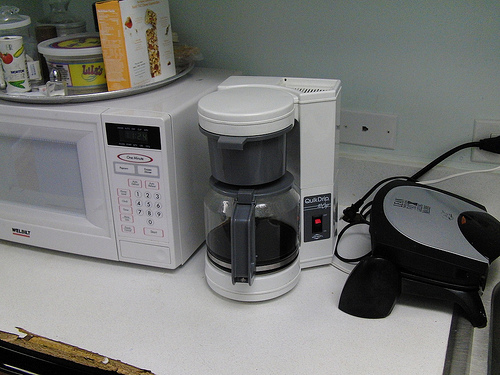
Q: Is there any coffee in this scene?
A: Yes, there is coffee.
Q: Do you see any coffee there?
A: Yes, there is coffee.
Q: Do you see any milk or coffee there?
A: Yes, there is coffee.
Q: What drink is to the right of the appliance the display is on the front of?
A: The drink is coffee.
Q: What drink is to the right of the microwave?
A: The drink is coffee.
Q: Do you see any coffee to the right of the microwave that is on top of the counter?
A: Yes, there is coffee to the right of the microwave.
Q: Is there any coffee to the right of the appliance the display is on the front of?
A: Yes, there is coffee to the right of the microwave.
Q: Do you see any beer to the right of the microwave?
A: No, there is coffee to the right of the microwave.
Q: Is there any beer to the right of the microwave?
A: No, there is coffee to the right of the microwave.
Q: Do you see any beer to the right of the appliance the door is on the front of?
A: No, there is coffee to the right of the microwave.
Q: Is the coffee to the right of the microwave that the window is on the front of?
A: Yes, the coffee is to the right of the microwave.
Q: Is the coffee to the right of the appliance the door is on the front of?
A: Yes, the coffee is to the right of the microwave.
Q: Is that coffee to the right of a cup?
A: No, the coffee is to the right of the microwave.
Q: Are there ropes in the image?
A: No, there are no ropes.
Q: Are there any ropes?
A: No, there are no ropes.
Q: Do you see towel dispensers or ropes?
A: No, there are no ropes or towel dispensers.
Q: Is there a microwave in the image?
A: Yes, there is a microwave.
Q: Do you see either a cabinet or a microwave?
A: Yes, there is a microwave.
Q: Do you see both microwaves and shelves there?
A: No, there is a microwave but no shelves.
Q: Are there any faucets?
A: No, there are no faucets.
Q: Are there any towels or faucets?
A: No, there are no faucets or towels.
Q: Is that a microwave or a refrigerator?
A: That is a microwave.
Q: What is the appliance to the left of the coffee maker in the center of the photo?
A: The appliance is a microwave.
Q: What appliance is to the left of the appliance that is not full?
A: The appliance is a microwave.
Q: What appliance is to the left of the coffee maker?
A: The appliance is a microwave.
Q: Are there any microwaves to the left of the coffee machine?
A: Yes, there is a microwave to the left of the coffee machine.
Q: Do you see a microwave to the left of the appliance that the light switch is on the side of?
A: Yes, there is a microwave to the left of the coffee machine.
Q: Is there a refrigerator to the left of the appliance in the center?
A: No, there is a microwave to the left of the coffee maker.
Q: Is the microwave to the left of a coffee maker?
A: Yes, the microwave is to the left of a coffee maker.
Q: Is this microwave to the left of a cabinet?
A: No, the microwave is to the left of a coffee maker.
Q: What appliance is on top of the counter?
A: The appliance is a microwave.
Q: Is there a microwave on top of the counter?
A: Yes, there is a microwave on top of the counter.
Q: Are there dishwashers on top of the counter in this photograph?
A: No, there is a microwave on top of the counter.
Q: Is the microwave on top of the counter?
A: Yes, the microwave is on top of the counter.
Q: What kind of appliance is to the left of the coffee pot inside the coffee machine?
A: The appliance is a microwave.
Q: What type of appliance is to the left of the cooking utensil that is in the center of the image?
A: The appliance is a microwave.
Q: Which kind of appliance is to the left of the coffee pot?
A: The appliance is a microwave.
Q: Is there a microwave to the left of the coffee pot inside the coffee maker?
A: Yes, there is a microwave to the left of the coffee pot.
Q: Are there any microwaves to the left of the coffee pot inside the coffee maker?
A: Yes, there is a microwave to the left of the coffee pot.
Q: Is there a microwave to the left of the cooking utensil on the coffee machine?
A: Yes, there is a microwave to the left of the coffee pot.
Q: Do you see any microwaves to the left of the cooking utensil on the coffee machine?
A: Yes, there is a microwave to the left of the coffee pot.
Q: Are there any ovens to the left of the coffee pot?
A: No, there is a microwave to the left of the coffee pot.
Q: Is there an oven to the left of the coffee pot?
A: No, there is a microwave to the left of the coffee pot.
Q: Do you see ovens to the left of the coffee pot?
A: No, there is a microwave to the left of the coffee pot.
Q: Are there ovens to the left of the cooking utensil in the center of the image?
A: No, there is a microwave to the left of the coffee pot.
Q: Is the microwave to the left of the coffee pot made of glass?
A: Yes, the microwave is to the left of the coffee pot.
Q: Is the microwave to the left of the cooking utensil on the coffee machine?
A: Yes, the microwave is to the left of the coffee pot.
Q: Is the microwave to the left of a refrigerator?
A: No, the microwave is to the left of the coffee pot.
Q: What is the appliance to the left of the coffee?
A: The appliance is a microwave.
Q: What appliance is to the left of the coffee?
A: The appliance is a microwave.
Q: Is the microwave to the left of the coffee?
A: Yes, the microwave is to the left of the coffee.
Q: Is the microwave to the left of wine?
A: No, the microwave is to the left of the coffee.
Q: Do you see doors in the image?
A: Yes, there is a door.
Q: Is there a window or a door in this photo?
A: Yes, there is a door.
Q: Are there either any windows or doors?
A: Yes, there is a door.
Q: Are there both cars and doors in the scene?
A: No, there is a door but no cars.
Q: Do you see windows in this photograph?
A: Yes, there is a window.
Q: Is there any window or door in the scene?
A: Yes, there is a window.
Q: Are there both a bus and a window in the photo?
A: No, there is a window but no buses.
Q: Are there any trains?
A: No, there are no trains.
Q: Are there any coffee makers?
A: Yes, there is a coffee maker.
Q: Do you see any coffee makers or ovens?
A: Yes, there is a coffee maker.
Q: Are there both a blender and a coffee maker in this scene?
A: No, there is a coffee maker but no blenders.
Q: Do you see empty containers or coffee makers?
A: Yes, there is an empty coffee maker.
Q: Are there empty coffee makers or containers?
A: Yes, there is an empty coffee maker.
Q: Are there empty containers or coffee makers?
A: Yes, there is an empty coffee maker.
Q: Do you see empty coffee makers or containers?
A: Yes, there is an empty coffee maker.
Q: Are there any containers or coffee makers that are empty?
A: Yes, the coffee maker is empty.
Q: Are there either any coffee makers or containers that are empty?
A: Yes, the coffee maker is empty.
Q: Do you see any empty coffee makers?
A: Yes, there is an empty coffee maker.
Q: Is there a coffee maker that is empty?
A: Yes, there is a coffee maker that is empty.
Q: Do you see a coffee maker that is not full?
A: Yes, there is a empty coffee maker.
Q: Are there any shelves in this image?
A: No, there are no shelves.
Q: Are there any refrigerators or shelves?
A: No, there are no shelves or refrigerators.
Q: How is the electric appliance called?
A: The appliance is a coffee maker.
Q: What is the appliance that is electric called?
A: The appliance is a coffee maker.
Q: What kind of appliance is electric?
A: The appliance is a coffee maker.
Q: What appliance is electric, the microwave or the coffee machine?
A: The coffee machine is electric.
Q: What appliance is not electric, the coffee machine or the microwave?
A: The microwave is not electric.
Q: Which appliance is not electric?
A: The appliance is a microwave.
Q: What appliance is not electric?
A: The appliance is a microwave.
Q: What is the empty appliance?
A: The appliance is a coffee maker.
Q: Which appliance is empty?
A: The appliance is a coffee maker.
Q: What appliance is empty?
A: The appliance is a coffee maker.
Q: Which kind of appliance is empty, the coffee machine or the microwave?
A: The coffee machine is empty.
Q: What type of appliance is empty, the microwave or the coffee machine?
A: The coffee machine is empty.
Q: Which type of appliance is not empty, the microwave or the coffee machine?
A: The microwave is not empty.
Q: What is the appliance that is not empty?
A: The appliance is a microwave.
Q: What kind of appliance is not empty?
A: The appliance is a microwave.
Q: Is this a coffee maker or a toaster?
A: This is a coffee maker.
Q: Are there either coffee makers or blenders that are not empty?
A: No, there is a coffee maker but it is empty.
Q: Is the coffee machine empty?
A: Yes, the coffee machine is empty.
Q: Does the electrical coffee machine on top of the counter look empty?
A: Yes, the coffee maker is empty.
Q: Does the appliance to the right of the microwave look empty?
A: Yes, the coffee maker is empty.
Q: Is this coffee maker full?
A: No, the coffee maker is empty.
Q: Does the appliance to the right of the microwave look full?
A: No, the coffee maker is empty.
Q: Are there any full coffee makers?
A: No, there is a coffee maker but it is empty.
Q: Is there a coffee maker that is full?
A: No, there is a coffee maker but it is empty.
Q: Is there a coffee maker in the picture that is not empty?
A: No, there is a coffee maker but it is empty.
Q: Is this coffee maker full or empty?
A: The coffee maker is empty.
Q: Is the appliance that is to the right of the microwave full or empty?
A: The coffee maker is empty.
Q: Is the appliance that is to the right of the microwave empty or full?
A: The coffee maker is empty.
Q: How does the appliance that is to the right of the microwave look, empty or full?
A: The coffee maker is empty.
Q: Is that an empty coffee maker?
A: Yes, that is an empty coffee maker.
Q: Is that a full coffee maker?
A: No, that is an empty coffee maker.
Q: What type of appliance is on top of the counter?
A: The appliance is a coffee maker.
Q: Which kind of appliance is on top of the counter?
A: The appliance is a coffee maker.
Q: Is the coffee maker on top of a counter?
A: Yes, the coffee maker is on top of a counter.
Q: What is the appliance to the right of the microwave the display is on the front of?
A: The appliance is a coffee maker.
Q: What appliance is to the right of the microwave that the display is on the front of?
A: The appliance is a coffee maker.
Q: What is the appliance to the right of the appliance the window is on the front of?
A: The appliance is a coffee maker.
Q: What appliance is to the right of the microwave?
A: The appliance is a coffee maker.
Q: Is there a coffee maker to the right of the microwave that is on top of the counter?
A: Yes, there is a coffee maker to the right of the microwave.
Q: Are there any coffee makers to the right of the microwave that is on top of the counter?
A: Yes, there is a coffee maker to the right of the microwave.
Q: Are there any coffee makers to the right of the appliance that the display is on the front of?
A: Yes, there is a coffee maker to the right of the microwave.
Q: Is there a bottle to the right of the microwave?
A: No, there is a coffee maker to the right of the microwave.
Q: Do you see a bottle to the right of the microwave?
A: No, there is a coffee maker to the right of the microwave.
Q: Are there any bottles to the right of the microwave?
A: No, there is a coffee maker to the right of the microwave.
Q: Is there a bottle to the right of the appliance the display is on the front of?
A: No, there is a coffee maker to the right of the microwave.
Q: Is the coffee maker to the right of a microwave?
A: Yes, the coffee maker is to the right of a microwave.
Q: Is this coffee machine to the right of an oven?
A: No, the coffee machine is to the right of a microwave.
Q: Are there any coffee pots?
A: Yes, there is a coffee pot.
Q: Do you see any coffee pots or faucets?
A: Yes, there is a coffee pot.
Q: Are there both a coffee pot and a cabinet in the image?
A: No, there is a coffee pot but no cabinets.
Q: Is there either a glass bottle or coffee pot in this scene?
A: Yes, there is a glass coffee pot.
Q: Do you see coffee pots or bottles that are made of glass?
A: Yes, the coffee pot is made of glass.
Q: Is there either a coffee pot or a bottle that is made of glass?
A: Yes, the coffee pot is made of glass.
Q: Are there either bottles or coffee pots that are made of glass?
A: Yes, the coffee pot is made of glass.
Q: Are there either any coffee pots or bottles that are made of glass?
A: Yes, the coffee pot is made of glass.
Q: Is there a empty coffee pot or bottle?
A: Yes, there is an empty coffee pot.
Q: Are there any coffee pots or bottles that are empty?
A: Yes, the coffee pot is empty.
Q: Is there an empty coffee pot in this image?
A: Yes, there is an empty coffee pot.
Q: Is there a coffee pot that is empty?
A: Yes, there is a coffee pot that is empty.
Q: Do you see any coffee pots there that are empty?
A: Yes, there is a coffee pot that is empty.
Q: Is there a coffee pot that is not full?
A: Yes, there is a empty coffee pot.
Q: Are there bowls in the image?
A: No, there are no bowls.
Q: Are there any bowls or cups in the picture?
A: No, there are no bowls or cups.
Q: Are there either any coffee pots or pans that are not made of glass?
A: No, there is a coffee pot but it is made of glass.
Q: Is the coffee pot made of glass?
A: Yes, the coffee pot is made of glass.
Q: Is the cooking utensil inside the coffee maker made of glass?
A: Yes, the coffee pot is made of glass.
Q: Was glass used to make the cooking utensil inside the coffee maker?
A: Yes, the coffee pot is made of glass.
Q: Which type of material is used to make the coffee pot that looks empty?
A: The coffee pot is made of glass.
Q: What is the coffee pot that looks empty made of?
A: The coffee pot is made of glass.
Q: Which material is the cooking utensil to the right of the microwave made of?
A: The coffee pot is made of glass.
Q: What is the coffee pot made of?
A: The coffee pot is made of glass.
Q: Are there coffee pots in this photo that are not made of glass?
A: No, there is a coffee pot but it is made of glass.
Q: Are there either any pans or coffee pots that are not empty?
A: No, there is a coffee pot but it is empty.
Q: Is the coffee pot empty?
A: Yes, the coffee pot is empty.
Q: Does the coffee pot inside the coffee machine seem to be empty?
A: Yes, the coffee pot is empty.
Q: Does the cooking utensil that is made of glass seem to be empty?
A: Yes, the coffee pot is empty.